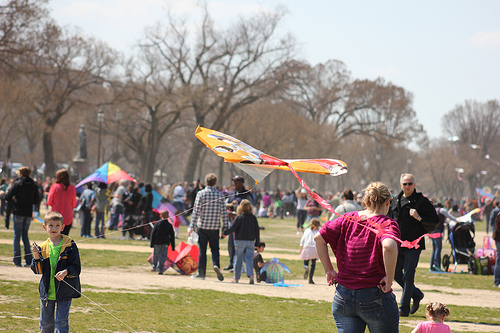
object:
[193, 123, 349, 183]
kite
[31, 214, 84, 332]
boy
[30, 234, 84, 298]
coat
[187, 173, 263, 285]
couple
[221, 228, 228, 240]
hands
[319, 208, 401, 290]
shirt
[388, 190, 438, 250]
jacket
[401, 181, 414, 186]
sunglasses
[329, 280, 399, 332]
jeans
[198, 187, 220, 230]
plaid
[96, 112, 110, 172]
post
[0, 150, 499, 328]
park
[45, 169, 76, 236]
people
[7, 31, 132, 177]
trees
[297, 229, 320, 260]
blouse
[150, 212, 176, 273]
person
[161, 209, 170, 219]
head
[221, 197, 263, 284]
woman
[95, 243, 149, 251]
dirt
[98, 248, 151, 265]
grass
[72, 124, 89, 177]
statue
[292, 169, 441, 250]
tail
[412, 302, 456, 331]
girl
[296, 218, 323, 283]
child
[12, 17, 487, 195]
background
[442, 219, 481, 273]
stroller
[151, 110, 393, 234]
air